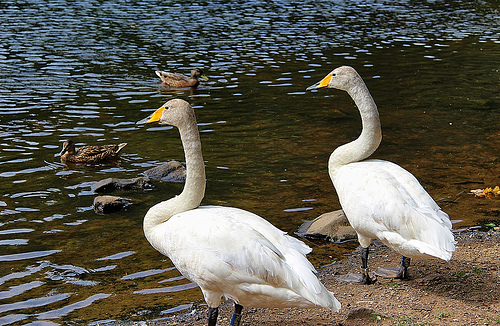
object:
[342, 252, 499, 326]
ground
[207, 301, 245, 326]
legs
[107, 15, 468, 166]
water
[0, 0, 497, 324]
water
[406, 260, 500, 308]
shadow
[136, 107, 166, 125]
beak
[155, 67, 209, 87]
duck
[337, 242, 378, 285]
foot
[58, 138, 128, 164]
duck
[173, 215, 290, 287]
white feathers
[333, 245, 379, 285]
webbed feet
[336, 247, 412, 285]
feet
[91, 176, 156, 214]
rocks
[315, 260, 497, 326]
shore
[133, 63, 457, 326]
geese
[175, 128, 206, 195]
neck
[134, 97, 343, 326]
bird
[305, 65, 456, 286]
bird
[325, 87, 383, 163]
neck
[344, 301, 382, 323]
dirt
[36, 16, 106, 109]
stones